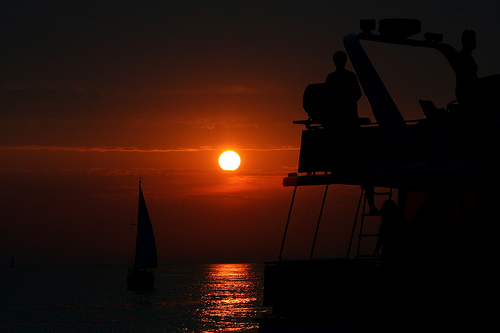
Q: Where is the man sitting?
A: On a boat deck.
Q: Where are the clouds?
A: Above and below the sun.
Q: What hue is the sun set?
A: Orange.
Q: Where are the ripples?
A: On the water.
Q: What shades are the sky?
A: Brown and orange, and reds.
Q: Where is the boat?
A: In water.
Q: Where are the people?
A: On boat.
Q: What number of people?
A: Four.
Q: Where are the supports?
A: Under platform.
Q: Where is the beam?
A: Behind person.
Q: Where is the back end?
A: On boat.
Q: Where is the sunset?
A: Over lake.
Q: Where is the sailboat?
A: On lake.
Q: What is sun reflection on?
A: Water.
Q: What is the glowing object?
A: Sun.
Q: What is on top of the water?
A: Sailboat.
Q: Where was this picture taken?
A: By the water.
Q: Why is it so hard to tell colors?
A: Everything is in silhouette.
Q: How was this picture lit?
A: Sunlight.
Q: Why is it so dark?
A: Sunset.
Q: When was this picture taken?
A: Evening.